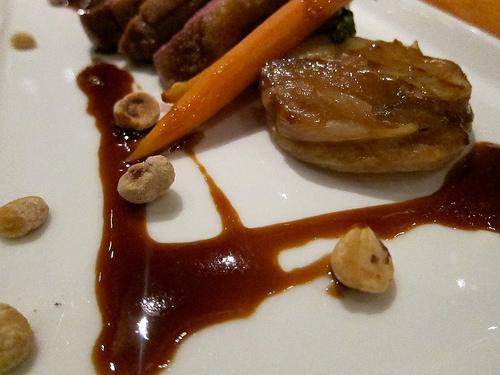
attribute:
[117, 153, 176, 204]
peanut — tan, large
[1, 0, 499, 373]
plate — white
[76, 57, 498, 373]
sauce — reflecting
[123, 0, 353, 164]
carrot — orange, long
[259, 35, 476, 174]
pastry — reflective, brown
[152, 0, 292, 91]
meat — dark, brown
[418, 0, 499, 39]
table — brown